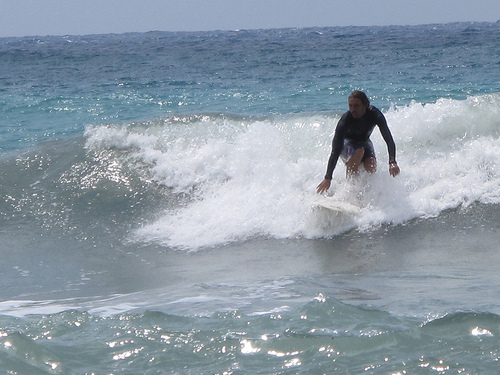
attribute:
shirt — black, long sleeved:
[322, 100, 400, 181]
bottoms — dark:
[332, 137, 381, 168]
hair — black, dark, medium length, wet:
[346, 90, 372, 111]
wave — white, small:
[80, 91, 499, 242]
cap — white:
[85, 89, 498, 256]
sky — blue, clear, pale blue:
[1, 1, 498, 40]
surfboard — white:
[296, 191, 375, 219]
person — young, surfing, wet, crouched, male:
[317, 88, 403, 201]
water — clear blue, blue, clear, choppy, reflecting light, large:
[13, 20, 486, 374]